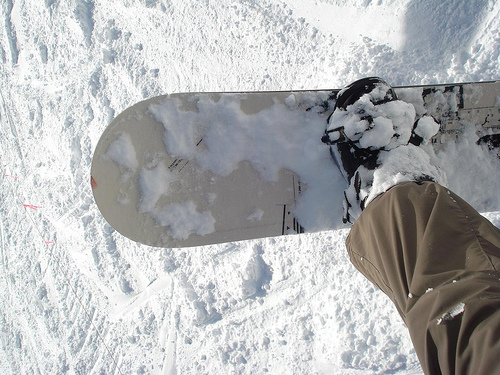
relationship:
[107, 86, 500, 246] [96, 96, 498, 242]
snow on board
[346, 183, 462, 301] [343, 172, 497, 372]
wrinkles on pants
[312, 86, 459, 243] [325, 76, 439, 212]
snow on boot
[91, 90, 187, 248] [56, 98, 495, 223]
tip of board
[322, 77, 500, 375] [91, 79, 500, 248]
person on a board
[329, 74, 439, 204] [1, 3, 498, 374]
boot covered in snow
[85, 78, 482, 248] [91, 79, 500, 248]
snow on board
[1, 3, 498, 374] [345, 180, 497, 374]
snow on pant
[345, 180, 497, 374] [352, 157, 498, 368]
pant on leg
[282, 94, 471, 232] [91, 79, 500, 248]
stripes on board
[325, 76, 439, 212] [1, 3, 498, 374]
boot covered in snow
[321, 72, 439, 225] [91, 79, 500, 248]
shoe on board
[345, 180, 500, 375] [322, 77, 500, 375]
pant on person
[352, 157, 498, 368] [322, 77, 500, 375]
leg of person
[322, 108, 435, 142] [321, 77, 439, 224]
strap on shoe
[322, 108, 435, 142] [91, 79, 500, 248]
strap on board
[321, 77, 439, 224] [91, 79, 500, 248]
shoe on board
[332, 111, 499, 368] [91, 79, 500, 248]
person on a board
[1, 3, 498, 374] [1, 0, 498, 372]
snow on hill side